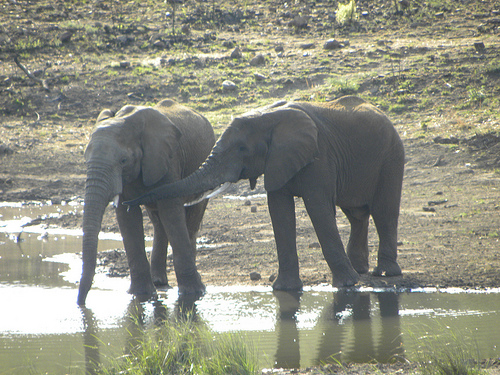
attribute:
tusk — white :
[181, 180, 233, 208]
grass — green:
[95, 310, 245, 374]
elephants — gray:
[216, 100, 431, 311]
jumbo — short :
[65, 106, 219, 306]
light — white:
[205, 271, 250, 317]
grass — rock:
[190, 30, 262, 88]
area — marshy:
[15, 275, 488, 360]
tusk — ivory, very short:
[108, 195, 123, 215]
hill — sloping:
[16, 6, 497, 129]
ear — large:
[264, 106, 317, 192]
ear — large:
[139, 106, 181, 182]